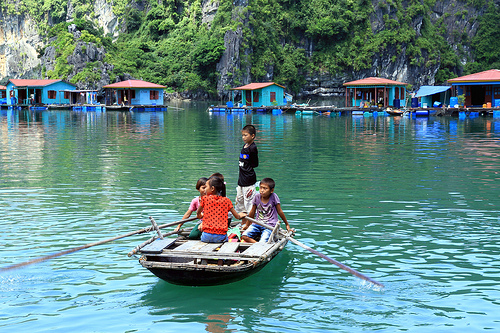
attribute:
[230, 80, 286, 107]
hut — blue, small, floating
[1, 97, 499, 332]
river — calm, green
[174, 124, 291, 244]
children — small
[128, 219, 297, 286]
boat — small, wooden, floating, hers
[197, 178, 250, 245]
girl — very young, young, little, rowing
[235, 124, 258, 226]
boy — young, standing, small, riding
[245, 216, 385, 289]
an oar — long, in action, useful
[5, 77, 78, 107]
hut — small, blue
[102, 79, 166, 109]
hut — small, blue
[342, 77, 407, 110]
hut — small, blue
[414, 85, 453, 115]
hut — small, blue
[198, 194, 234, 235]
blouse — red, black, orange, pink, dotted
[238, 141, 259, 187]
t-shirt — black, dark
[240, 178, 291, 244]
boy — young, looking, in purple, sitting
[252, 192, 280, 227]
shirt — purple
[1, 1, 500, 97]
vegetation — beautiful, green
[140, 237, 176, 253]
board — wood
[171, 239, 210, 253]
board — wood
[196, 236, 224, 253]
board — wood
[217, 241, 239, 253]
board — wood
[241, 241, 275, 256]
board — wood